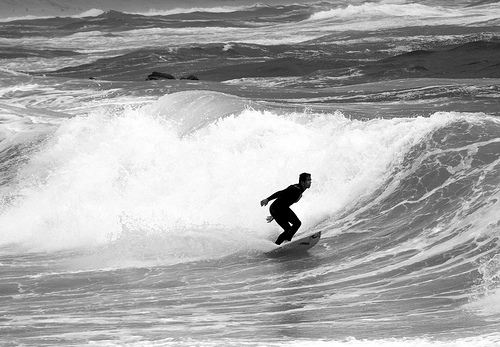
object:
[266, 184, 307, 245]
swim suit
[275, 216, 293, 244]
leg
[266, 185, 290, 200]
arm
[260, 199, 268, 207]
hand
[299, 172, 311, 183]
hair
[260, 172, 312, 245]
guy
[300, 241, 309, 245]
design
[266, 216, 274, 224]
left hand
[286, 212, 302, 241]
left leg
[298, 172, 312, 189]
head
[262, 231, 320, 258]
surfboard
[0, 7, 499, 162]
ripples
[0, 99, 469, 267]
spray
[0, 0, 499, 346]
ocean